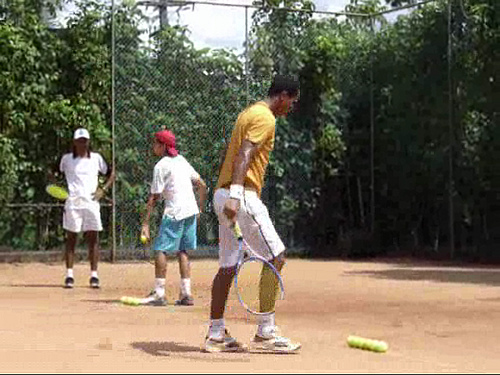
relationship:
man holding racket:
[192, 81, 315, 356] [228, 218, 283, 316]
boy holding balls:
[137, 130, 207, 306] [367, 340, 380, 351]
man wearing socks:
[199, 78, 302, 357] [206, 312, 276, 341]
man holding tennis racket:
[58, 125, 116, 288] [42, 183, 70, 202]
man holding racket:
[199, 78, 302, 357] [225, 211, 286, 318]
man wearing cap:
[192, 81, 315, 356] [150, 127, 180, 158]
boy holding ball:
[137, 130, 207, 306] [136, 231, 146, 245]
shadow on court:
[341, 267, 498, 288] [1, 256, 498, 373]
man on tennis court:
[199, 78, 302, 357] [2, 257, 481, 372]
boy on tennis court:
[137, 130, 207, 306] [2, 257, 481, 372]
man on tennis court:
[58, 125, 116, 288] [2, 257, 481, 372]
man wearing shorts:
[199, 78, 302, 357] [211, 187, 288, 270]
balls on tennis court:
[338, 331, 391, 355] [2, 257, 481, 372]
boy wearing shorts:
[118, 122, 196, 301] [153, 215, 199, 259]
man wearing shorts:
[46, 119, 123, 297] [55, 207, 105, 235]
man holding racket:
[46, 119, 123, 297] [42, 180, 89, 205]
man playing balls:
[199, 78, 302, 357] [360, 340, 373, 351]